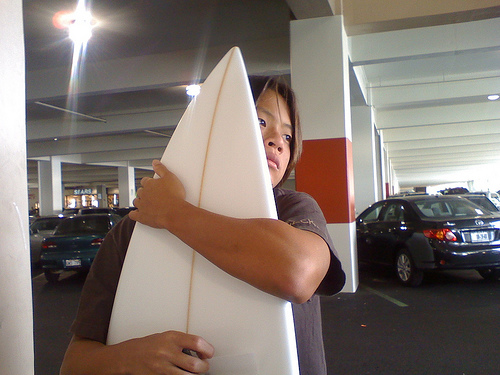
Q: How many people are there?
A: 1.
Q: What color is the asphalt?
A: Black.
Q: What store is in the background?
A: Sears.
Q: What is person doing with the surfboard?
A: Holding it.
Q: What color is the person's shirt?
A: Brown.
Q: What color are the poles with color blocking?
A: White and red.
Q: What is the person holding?
A: Surfboard.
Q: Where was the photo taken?
A: Parking garage.